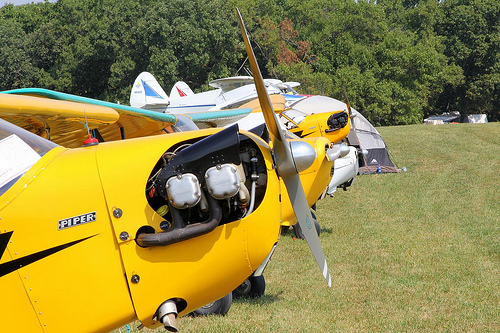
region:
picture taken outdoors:
[34, 11, 494, 308]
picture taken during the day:
[31, 17, 448, 308]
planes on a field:
[30, 11, 433, 268]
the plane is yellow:
[43, 101, 318, 292]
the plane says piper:
[34, 200, 124, 253]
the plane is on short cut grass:
[243, 159, 489, 330]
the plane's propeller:
[81, 46, 433, 223]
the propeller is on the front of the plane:
[204, 56, 399, 287]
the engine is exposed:
[139, 148, 301, 238]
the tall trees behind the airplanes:
[83, 19, 428, 51]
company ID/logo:
[47, 207, 103, 230]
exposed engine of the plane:
[127, 137, 267, 237]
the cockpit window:
[0, 105, 65, 180]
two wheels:
[185, 262, 270, 318]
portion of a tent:
[357, 95, 412, 181]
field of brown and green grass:
[361, 185, 491, 311]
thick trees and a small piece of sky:
[0, 0, 95, 37]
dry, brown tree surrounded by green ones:
[262, 5, 322, 70]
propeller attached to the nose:
[256, 115, 317, 192]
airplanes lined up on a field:
[5, 12, 353, 312]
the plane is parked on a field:
[0, 82, 283, 332]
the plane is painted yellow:
[5, 115, 275, 332]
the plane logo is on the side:
[56, 210, 100, 233]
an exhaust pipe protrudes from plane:
[160, 299, 184, 330]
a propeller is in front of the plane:
[236, 11, 338, 293]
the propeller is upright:
[231, 8, 343, 291]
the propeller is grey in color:
[234, 10, 334, 295]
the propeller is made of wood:
[234, 11, 341, 293]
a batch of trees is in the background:
[2, 1, 497, 135]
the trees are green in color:
[3, 1, 498, 127]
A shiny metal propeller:
[209, 0, 356, 288]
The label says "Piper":
[55, 206, 101, 228]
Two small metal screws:
[110, 203, 129, 241]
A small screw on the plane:
[128, 269, 140, 289]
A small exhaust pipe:
[153, 297, 181, 327]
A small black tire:
[197, 292, 236, 314]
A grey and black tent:
[276, 87, 412, 172]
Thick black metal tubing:
[140, 211, 227, 247]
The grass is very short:
[358, 248, 474, 311]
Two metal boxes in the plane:
[166, 162, 238, 211]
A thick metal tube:
[142, 214, 232, 246]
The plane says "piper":
[53, 212, 104, 228]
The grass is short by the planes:
[363, 221, 473, 313]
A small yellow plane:
[0, 123, 297, 327]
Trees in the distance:
[314, 16, 455, 108]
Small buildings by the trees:
[425, 105, 484, 127]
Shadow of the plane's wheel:
[248, 287, 289, 309]